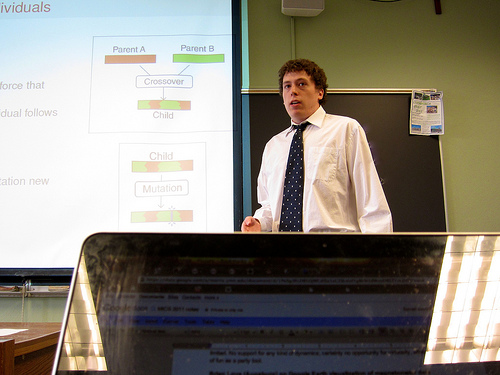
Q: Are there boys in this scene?
A: No, there are no boys.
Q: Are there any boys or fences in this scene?
A: No, there are no boys or fences.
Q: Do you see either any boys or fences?
A: No, there are no boys or fences.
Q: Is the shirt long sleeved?
A: Yes, the shirt is long sleeved.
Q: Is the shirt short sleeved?
A: No, the shirt is long sleeved.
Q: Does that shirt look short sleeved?
A: No, the shirt is long sleeved.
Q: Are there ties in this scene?
A: Yes, there is a tie.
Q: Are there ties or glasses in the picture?
A: Yes, there is a tie.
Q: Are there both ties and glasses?
A: No, there is a tie but no glasses.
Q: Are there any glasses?
A: No, there are no glasses.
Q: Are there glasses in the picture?
A: No, there are no glasses.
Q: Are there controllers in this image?
A: No, there are no controllers.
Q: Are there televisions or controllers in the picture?
A: No, there are no controllers or televisions.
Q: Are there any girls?
A: No, there are no girls.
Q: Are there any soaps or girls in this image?
A: No, there are no girls or soaps.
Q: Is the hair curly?
A: Yes, the hair is curly.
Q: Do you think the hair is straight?
A: No, the hair is curly.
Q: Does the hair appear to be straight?
A: No, the hair is curly.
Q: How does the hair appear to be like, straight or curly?
A: The hair is curly.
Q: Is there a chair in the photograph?
A: No, there are no chairs.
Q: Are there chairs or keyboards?
A: No, there are no chairs or keyboards.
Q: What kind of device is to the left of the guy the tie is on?
A: The device is a screen.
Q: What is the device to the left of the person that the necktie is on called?
A: The device is a screen.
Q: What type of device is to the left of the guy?
A: The device is a screen.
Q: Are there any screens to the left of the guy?
A: Yes, there is a screen to the left of the guy.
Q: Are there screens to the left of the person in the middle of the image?
A: Yes, there is a screen to the left of the guy.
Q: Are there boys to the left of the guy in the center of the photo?
A: No, there is a screen to the left of the guy.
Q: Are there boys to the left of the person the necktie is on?
A: No, there is a screen to the left of the guy.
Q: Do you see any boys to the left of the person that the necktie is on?
A: No, there is a screen to the left of the guy.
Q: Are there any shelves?
A: No, there are no shelves.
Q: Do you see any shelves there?
A: No, there are no shelves.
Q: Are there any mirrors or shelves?
A: No, there are no shelves or mirrors.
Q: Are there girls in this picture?
A: No, there are no girls.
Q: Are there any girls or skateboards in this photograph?
A: No, there are no girls or skateboards.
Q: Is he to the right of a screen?
A: Yes, the guy is to the right of a screen.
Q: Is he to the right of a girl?
A: No, the guy is to the right of a screen.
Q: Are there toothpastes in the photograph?
A: No, there are no toothpastes.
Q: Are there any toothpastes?
A: No, there are no toothpastes.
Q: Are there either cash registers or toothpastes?
A: No, there are no toothpastes or cash registers.